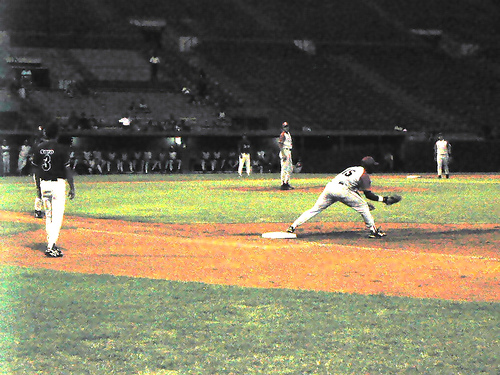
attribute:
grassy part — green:
[146, 277, 225, 321]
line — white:
[11, 202, 499, 289]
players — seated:
[69, 140, 264, 169]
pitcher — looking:
[271, 109, 301, 205]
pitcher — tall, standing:
[273, 120, 298, 198]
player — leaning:
[282, 150, 406, 248]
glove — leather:
[381, 186, 408, 215]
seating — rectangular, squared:
[48, 57, 219, 122]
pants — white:
[282, 181, 373, 232]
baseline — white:
[0, 217, 500, 265]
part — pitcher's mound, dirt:
[227, 179, 319, 193]